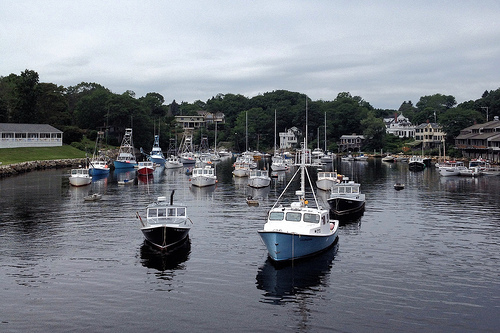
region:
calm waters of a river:
[56, 242, 106, 285]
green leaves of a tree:
[16, 70, 41, 85]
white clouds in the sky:
[373, 30, 433, 75]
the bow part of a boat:
[263, 228, 285, 243]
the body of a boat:
[309, 238, 329, 250]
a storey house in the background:
[418, 125, 432, 136]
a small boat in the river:
[246, 196, 258, 204]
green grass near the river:
[13, 152, 42, 156]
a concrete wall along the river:
[8, 164, 34, 169]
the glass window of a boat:
[291, 214, 299, 219]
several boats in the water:
[35, 102, 482, 232]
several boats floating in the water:
[41, 138, 446, 251]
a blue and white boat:
[254, 191, 344, 273]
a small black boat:
[127, 196, 196, 268]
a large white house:
[380, 106, 412, 148]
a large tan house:
[411, 115, 451, 151]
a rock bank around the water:
[0, 154, 88, 179]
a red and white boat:
[134, 156, 159, 178]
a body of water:
[380, 185, 489, 326]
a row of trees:
[102, 89, 372, 135]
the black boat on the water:
[123, 187, 203, 259]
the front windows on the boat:
[264, 209, 323, 226]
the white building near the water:
[0, 120, 63, 147]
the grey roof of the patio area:
[1, 120, 67, 136]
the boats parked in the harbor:
[65, 136, 498, 291]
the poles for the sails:
[242, 105, 332, 145]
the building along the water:
[455, 118, 499, 168]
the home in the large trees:
[169, 96, 227, 141]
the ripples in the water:
[347, 256, 473, 330]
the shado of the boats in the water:
[116, 248, 346, 331]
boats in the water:
[73, 120, 421, 279]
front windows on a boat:
[267, 210, 319, 222]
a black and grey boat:
[134, 200, 193, 255]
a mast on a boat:
[294, 98, 314, 208]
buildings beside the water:
[360, 98, 499, 183]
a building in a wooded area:
[147, 98, 235, 149]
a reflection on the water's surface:
[248, 265, 339, 313]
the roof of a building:
[460, 130, 487, 140]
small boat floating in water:
[134, 203, 198, 268]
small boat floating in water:
[258, 212, 323, 265]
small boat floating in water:
[330, 183, 355, 215]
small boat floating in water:
[318, 160, 335, 185]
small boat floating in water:
[250, 172, 270, 196]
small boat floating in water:
[278, 148, 295, 176]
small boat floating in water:
[235, 155, 246, 175]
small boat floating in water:
[187, 166, 207, 193]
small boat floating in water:
[141, 165, 153, 180]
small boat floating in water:
[68, 163, 99, 193]